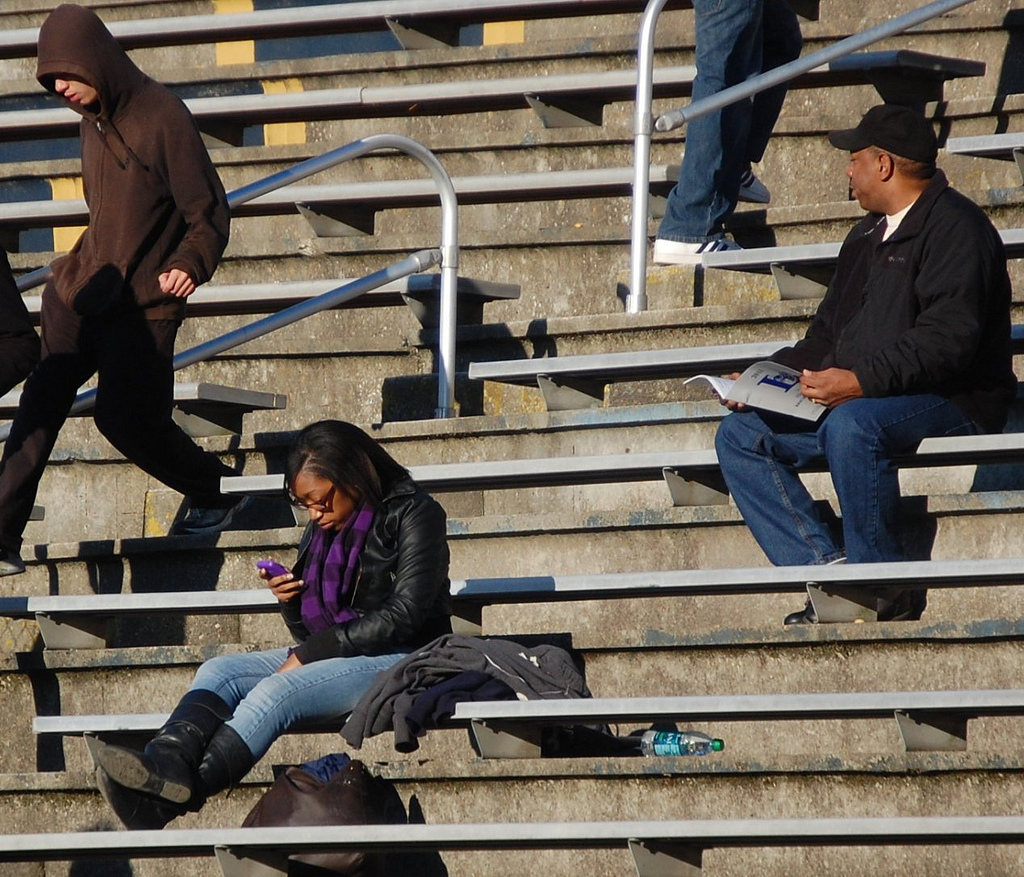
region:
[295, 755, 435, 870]
the lady's handbag is down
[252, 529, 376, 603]
THE GIRL HAS A PURPLE SCARF AROUND HER NECK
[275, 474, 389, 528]
THE WOMAN IS WEARING GLASSES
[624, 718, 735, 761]
THERES A DASANI WATER LAYING ON THE GROUND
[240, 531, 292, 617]
THE WOMAN IS USING THE PHONE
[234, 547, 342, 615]
THE PHONE IS PURPLE IN THE LADY RIGHT HAND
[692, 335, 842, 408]
THE MAN HAS A BOOK IN HIS HANDS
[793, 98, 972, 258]
THE MAN IS BLACK THATS LOOKING AROUND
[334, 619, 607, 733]
THE LADY JACKET IS BESIDE HER HIP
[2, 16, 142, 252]
THE BOY IS WEARING A BROWN HOODIE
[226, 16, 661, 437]
metal bleachers with railing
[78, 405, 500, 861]
woman texting on a purple phone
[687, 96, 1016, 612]
man with a hat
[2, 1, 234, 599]
kid with a hoodie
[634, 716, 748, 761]
water bottle on it's side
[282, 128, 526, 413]
silver colored metal railing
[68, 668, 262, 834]
black boots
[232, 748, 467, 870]
bag on bleachers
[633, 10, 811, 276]
man's legs with shoes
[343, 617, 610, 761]
jackets on a bench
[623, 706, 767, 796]
water bottle with green top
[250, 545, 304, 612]
a purple cell phone in a right hand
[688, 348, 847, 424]
an open booklet being held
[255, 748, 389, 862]
a ladies brown handbag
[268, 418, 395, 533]
a woman wearing eyeglasses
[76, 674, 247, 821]
a pair of black ladies boots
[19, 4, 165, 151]
a boy with a hooded jacked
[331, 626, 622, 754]
a gray jacket or sweater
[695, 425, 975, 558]
a mans legs wearing denim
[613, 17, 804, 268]
a person climbing stairs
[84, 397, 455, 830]
not interester in the nearby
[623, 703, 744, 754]
not from an environmentalist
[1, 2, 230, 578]
lesson from Travon not learned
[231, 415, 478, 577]
not wearing contact lens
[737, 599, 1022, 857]
these bleachers are aluminum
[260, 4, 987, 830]
denim is the style for the day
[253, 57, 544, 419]
a handrail in the stands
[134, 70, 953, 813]
this game is not a sellout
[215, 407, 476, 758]
woman looking at her purple cell phone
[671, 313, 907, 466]
a white catalog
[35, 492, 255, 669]
a shadow on stairs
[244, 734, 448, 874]
a handbag stuffed full of things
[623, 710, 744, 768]
a plastic water bottle on its side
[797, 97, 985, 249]
man wearing a black cap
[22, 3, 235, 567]
man wearing a brown zipped hoodie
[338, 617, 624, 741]
a gray sweatshirt on the stairs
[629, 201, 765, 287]
a white adidas shoe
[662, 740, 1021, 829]
concrete steps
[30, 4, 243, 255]
He is wearing a hoodie.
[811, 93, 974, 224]
He is wearing a cap.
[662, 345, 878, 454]
A booklet is in his hands.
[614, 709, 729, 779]
That's abottle of water.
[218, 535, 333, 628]
She is checking her cell phone.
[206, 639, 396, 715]
Her pants are denim.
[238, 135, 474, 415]
The railing is for safety.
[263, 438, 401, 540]
She has eyeglasses to see with.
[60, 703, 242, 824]
The boots are black.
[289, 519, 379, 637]
a woman has a purple scarf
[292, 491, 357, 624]
striped purple scarf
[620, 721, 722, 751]
fallen over plastic water bottle